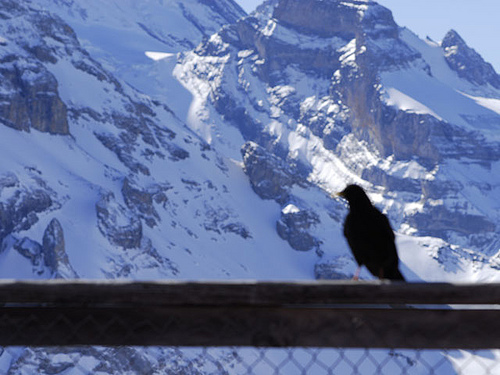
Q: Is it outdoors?
A: Yes, it is outdoors.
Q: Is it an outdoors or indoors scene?
A: It is outdoors.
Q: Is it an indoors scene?
A: No, it is outdoors.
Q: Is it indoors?
A: No, it is outdoors.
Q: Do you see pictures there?
A: No, there are no pictures.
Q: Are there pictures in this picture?
A: No, there are no pictures.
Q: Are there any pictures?
A: No, there are no pictures.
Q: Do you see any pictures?
A: No, there are no pictures.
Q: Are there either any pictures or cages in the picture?
A: No, there are no pictures or cages.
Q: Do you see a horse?
A: No, there are no horses.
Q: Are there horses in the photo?
A: No, there are no horses.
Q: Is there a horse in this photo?
A: No, there are no horses.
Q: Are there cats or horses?
A: No, there are no horses or cats.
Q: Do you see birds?
A: Yes, there is a bird.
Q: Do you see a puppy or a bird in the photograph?
A: Yes, there is a bird.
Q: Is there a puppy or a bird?
A: Yes, there is a bird.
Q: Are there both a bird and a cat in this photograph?
A: No, there is a bird but no cats.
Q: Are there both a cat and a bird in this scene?
A: No, there is a bird but no cats.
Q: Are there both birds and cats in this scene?
A: No, there is a bird but no cats.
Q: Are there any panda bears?
A: No, there are no panda bears.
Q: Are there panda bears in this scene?
A: No, there are no panda bears.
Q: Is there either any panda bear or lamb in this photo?
A: No, there are no panda bears or lambs.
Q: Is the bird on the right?
A: Yes, the bird is on the right of the image.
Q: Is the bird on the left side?
A: No, the bird is on the right of the image.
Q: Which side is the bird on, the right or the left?
A: The bird is on the right of the image.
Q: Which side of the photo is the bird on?
A: The bird is on the right of the image.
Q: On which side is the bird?
A: The bird is on the right of the image.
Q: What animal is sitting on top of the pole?
A: The animal is a bird.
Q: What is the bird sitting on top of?
A: The bird is sitting on top of the pole.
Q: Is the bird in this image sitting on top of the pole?
A: Yes, the bird is sitting on top of the pole.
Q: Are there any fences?
A: Yes, there is a fence.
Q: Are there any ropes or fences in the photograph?
A: Yes, there is a fence.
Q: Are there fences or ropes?
A: Yes, there is a fence.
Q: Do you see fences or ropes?
A: Yes, there is a fence.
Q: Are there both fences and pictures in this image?
A: No, there is a fence but no pictures.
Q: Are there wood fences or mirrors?
A: Yes, there is a wood fence.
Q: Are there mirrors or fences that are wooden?
A: Yes, the fence is wooden.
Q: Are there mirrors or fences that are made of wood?
A: Yes, the fence is made of wood.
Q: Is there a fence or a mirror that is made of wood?
A: Yes, the fence is made of wood.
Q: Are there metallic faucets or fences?
A: Yes, there is a metal fence.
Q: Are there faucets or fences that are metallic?
A: Yes, the fence is metallic.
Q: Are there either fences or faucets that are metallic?
A: Yes, the fence is metallic.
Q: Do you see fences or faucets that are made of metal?
A: Yes, the fence is made of metal.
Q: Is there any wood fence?
A: Yes, there is a wood fence.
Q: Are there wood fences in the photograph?
A: Yes, there is a wood fence.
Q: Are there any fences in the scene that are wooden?
A: Yes, there is a fence that is wooden.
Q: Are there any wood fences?
A: Yes, there is a fence that is made of wood.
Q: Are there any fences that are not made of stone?
A: Yes, there is a fence that is made of wood.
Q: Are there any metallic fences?
A: Yes, there is a metal fence.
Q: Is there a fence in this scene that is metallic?
A: Yes, there is a fence that is metallic.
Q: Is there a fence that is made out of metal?
A: Yes, there is a fence that is made of metal.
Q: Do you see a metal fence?
A: Yes, there is a fence that is made of metal.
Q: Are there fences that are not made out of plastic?
A: Yes, there is a fence that is made of metal.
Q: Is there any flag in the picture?
A: No, there are no flags.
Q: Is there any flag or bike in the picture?
A: No, there are no flags or bikes.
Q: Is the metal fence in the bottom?
A: Yes, the fence is in the bottom of the image.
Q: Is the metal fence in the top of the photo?
A: No, the fence is in the bottom of the image.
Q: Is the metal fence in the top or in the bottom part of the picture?
A: The fence is in the bottom of the image.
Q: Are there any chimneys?
A: No, there are no chimneys.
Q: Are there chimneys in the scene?
A: No, there are no chimneys.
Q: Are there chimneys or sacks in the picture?
A: No, there are no chimneys or sacks.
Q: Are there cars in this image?
A: No, there are no cars.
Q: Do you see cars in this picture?
A: No, there are no cars.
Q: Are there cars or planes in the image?
A: No, there are no cars or planes.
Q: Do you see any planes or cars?
A: No, there are no cars or planes.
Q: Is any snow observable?
A: Yes, there is snow.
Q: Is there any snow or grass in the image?
A: Yes, there is snow.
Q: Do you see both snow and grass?
A: No, there is snow but no grass.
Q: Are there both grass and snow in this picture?
A: No, there is snow but no grass.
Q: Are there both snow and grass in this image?
A: No, there is snow but no grass.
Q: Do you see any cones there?
A: No, there are no cones.